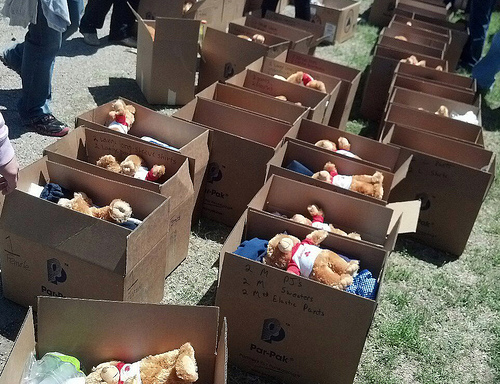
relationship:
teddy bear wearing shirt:
[260, 225, 361, 291] [284, 238, 323, 279]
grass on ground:
[417, 291, 456, 334] [416, 329, 473, 365]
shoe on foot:
[15, 110, 78, 147] [23, 89, 73, 130]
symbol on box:
[40, 246, 70, 280] [6, 214, 72, 269]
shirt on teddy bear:
[291, 245, 321, 265] [260, 229, 361, 290]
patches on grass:
[440, 322, 480, 363] [401, 319, 452, 357]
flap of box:
[390, 202, 437, 247] [350, 179, 435, 231]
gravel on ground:
[67, 57, 96, 80] [62, 56, 139, 87]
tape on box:
[157, 88, 193, 108] [140, 39, 191, 89]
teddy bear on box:
[299, 157, 413, 207] [273, 143, 333, 178]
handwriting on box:
[247, 263, 310, 313] [242, 301, 342, 381]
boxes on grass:
[120, 109, 399, 192] [404, 304, 487, 328]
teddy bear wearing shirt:
[310, 162, 383, 199] [323, 168, 356, 197]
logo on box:
[259, 310, 307, 363] [220, 266, 358, 362]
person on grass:
[12, 40, 69, 105] [67, 65, 110, 103]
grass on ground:
[0, 0, 499, 383] [410, 310, 464, 362]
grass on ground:
[0, 0, 499, 383] [372, 204, 499, 382]